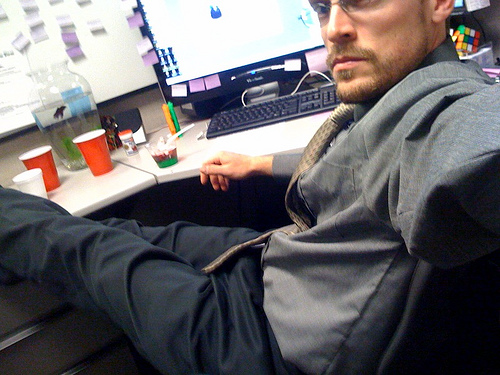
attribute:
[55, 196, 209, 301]
pants — black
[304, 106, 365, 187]
tie — brown, gold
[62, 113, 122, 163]
cup — red, disponsable, sitting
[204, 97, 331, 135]
keyboard — black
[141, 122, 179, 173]
parfait — dessert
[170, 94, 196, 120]
highlighters — green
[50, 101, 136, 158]
fish — beta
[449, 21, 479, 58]
cube — sitting, unsolved, rubix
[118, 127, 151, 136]
food — fish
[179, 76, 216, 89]
post it — purple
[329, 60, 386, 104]
beard — here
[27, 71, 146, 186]
bowl — fish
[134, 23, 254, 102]
note — sticking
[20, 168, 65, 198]
cup — white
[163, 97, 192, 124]
markit — green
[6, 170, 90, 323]
feet — up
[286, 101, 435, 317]
suit — worn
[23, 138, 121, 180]
cups — red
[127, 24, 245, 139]
notes — purple